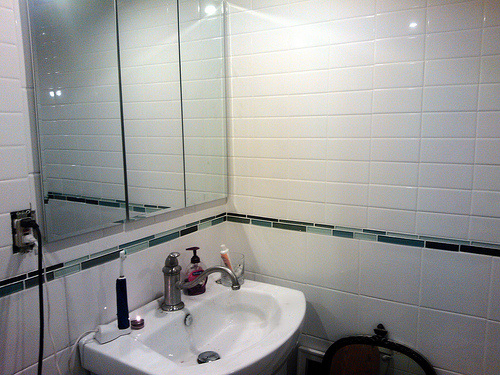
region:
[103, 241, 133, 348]
a electric toothbrush on a sink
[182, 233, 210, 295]
a bottle of hand soap on a sink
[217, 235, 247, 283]
a tube of toothpaste in a glass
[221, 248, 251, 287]
a clear drinking glass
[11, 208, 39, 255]
a electrical outlet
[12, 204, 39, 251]
a electrical outlet without a cover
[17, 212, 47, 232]
a black cord plugged into a electrical outlet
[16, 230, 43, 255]
a white cord plugged into a outlet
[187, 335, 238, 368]
a bathroom sink drain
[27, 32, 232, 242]
a mirror hanging on a wall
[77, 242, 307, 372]
white bathroom sink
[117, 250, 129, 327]
an electric toothbrush with blue handle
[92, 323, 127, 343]
charging base for the toothbrush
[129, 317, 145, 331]
tea light candle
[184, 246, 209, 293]
a bottle of purple hand soap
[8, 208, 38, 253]
electrical outlet with no cover plate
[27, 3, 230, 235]
mirror over the sink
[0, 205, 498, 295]
green tile stripe around bathroom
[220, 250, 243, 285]
small clear glass cup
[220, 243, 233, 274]
white and yellow tube inside of glass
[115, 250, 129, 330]
Electric toothbrush with black handle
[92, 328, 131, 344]
Electric toothbrush white charging base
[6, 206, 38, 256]
Electrical outlet without cover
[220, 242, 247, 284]
Glass holding a toothpaste tube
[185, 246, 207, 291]
Liquid hand soap dispenser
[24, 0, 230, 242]
Three-door mirror cabinet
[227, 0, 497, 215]
White subway tiles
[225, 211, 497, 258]
Border of green glass tiles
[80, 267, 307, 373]
White bathroom sink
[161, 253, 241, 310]
Nickel bathroom sink faucet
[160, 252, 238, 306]
A faucet on a sink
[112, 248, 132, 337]
An electronic toothbrush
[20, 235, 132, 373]
A toothbrush on a charging stand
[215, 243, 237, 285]
Toothpaste on a sink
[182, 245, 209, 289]
Soap in a bottle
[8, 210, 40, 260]
An outlet on a wall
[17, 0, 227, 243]
A mirror in a bathroom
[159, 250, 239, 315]
A metal faucet attached to a sink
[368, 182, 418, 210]
Piece of tile on a wall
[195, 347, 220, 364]
The drain on a sink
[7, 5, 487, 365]
Picture taken in a bathroom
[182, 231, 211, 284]
A soap dispenser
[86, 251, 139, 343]
An electronic toothbrush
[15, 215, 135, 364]
The toothbrush is charging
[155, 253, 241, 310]
A stainless steel faucet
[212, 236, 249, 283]
A glass cup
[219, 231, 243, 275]
There is a tube in the glass cup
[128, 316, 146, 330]
A small candle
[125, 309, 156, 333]
The candle is lit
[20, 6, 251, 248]
A mirror on the wall